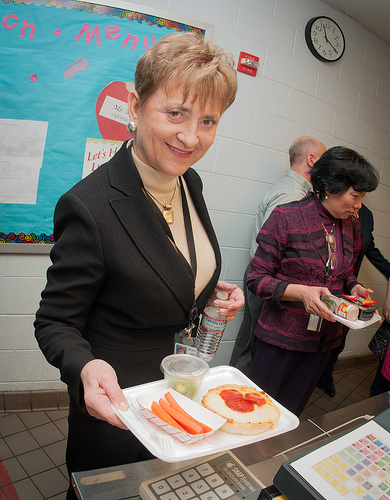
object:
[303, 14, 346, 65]
clock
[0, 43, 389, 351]
wall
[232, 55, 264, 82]
fire alarm device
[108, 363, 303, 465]
tray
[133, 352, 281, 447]
food to eat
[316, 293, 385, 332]
their food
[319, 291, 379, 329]
food to eat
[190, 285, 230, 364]
water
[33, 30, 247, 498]
woman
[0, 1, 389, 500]
cafeteria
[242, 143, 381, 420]
lady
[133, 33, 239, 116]
hairstyle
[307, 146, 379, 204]
hairstyle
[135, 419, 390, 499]
cash register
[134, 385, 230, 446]
paper boat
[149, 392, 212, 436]
carrot sticks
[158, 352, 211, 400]
cup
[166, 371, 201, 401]
kiwi slices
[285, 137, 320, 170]
hairstyle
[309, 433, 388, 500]
buttons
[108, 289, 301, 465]
sales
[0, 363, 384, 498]
flooring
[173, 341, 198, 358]
badge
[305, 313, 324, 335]
badge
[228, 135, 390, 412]
more people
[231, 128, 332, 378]
man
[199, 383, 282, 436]
pizza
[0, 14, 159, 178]
words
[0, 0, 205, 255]
bulletin board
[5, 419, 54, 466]
part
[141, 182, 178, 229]
necklace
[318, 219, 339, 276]
necklace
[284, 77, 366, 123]
portion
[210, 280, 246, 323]
hand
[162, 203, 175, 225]
gold pendant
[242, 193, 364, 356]
purple and black jac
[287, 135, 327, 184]
head and ear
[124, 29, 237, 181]
woman's head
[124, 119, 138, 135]
earring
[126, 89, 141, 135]
woman's ear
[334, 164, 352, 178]
portion